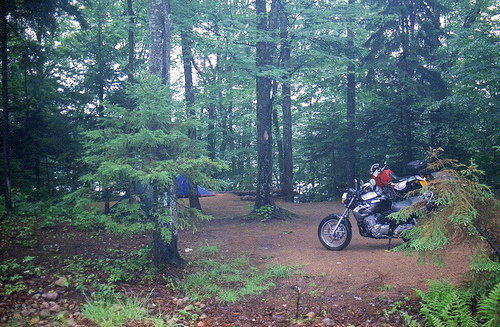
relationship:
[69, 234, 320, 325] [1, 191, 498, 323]
grass on ground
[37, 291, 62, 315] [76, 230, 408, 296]
stones on the ground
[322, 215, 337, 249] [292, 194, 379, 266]
part of a wheel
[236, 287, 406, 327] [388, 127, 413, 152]
part of a ground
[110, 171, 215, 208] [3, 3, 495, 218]
tent in woods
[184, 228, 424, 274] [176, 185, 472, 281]
patch of bare earth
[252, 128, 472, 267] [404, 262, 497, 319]
beautiful bright green ferns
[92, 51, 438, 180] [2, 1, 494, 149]
sky through trees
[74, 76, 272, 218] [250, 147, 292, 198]
moss growing on trunk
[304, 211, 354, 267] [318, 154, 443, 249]
front wheel of a bike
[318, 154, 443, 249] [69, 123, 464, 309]
bike are two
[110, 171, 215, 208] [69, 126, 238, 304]
tent are two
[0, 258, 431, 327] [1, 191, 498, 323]
pebbles are on ground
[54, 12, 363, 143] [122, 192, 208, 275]
trees are few meters apart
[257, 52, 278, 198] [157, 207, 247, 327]
bark tree bark grey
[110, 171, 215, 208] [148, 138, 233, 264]
tent blue in color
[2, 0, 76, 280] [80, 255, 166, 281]
trees are closely apart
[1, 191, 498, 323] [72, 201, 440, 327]
ground brown in color